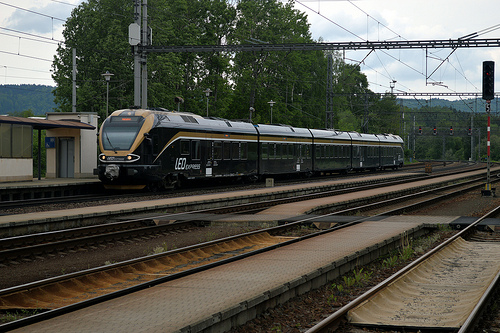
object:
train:
[92, 107, 405, 190]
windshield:
[103, 124, 142, 151]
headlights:
[101, 156, 131, 160]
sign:
[112, 117, 138, 122]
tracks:
[0, 159, 500, 333]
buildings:
[0, 110, 101, 179]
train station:
[0, 112, 408, 202]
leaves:
[81, 6, 311, 80]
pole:
[132, 0, 141, 109]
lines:
[0, 0, 77, 80]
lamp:
[100, 70, 115, 119]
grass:
[330, 223, 450, 302]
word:
[175, 158, 187, 170]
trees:
[49, 0, 500, 162]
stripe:
[161, 131, 403, 148]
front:
[98, 108, 151, 182]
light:
[481, 61, 496, 101]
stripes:
[151, 130, 402, 165]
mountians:
[0, 83, 500, 114]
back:
[399, 0, 500, 200]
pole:
[485, 103, 491, 194]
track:
[299, 201, 500, 333]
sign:
[45, 137, 56, 148]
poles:
[132, 0, 149, 110]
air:
[0, 0, 500, 333]